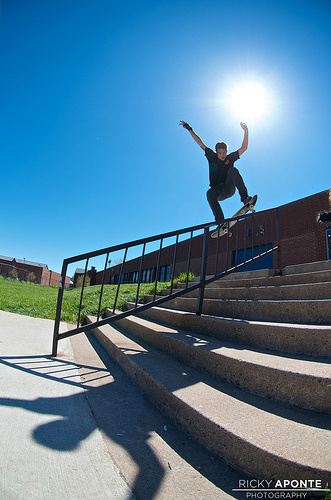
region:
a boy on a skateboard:
[169, 94, 282, 247]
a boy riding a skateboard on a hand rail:
[35, 114, 268, 322]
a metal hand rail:
[20, 187, 293, 350]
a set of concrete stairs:
[144, 267, 321, 433]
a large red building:
[15, 249, 60, 288]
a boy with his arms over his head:
[177, 102, 258, 176]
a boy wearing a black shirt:
[197, 133, 240, 181]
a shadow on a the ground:
[30, 317, 221, 489]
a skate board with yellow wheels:
[200, 193, 271, 240]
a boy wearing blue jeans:
[190, 128, 262, 228]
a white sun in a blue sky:
[7, 7, 328, 133]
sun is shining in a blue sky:
[170, 47, 317, 145]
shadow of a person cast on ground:
[1, 323, 229, 497]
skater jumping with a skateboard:
[174, 108, 268, 245]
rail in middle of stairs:
[43, 203, 293, 360]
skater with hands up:
[172, 108, 264, 229]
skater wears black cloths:
[175, 107, 262, 238]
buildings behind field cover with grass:
[1, 188, 329, 285]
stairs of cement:
[53, 210, 329, 498]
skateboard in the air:
[208, 189, 261, 249]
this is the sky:
[8, 11, 53, 43]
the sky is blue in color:
[8, 123, 84, 181]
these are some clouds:
[1, 212, 54, 250]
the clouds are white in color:
[20, 243, 48, 257]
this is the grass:
[15, 289, 52, 307]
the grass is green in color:
[26, 286, 47, 307]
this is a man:
[178, 109, 257, 216]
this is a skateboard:
[211, 194, 259, 238]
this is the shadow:
[5, 352, 117, 399]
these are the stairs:
[230, 282, 307, 393]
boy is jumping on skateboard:
[182, 115, 256, 225]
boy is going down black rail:
[15, 106, 269, 325]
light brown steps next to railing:
[126, 271, 308, 443]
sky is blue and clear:
[23, 32, 153, 187]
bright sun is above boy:
[201, 67, 292, 140]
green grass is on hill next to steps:
[5, 209, 161, 319]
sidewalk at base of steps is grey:
[12, 351, 87, 491]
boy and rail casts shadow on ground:
[18, 348, 141, 498]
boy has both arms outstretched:
[176, 114, 262, 152]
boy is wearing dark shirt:
[198, 144, 227, 183]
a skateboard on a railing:
[209, 193, 260, 237]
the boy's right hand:
[176, 118, 193, 131]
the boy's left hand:
[239, 119, 248, 129]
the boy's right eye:
[216, 149, 222, 156]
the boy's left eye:
[223, 149, 225, 156]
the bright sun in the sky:
[215, 70, 273, 125]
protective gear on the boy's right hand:
[182, 120, 192, 132]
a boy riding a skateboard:
[176, 114, 263, 237]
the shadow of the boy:
[0, 281, 265, 498]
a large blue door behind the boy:
[231, 239, 282, 273]